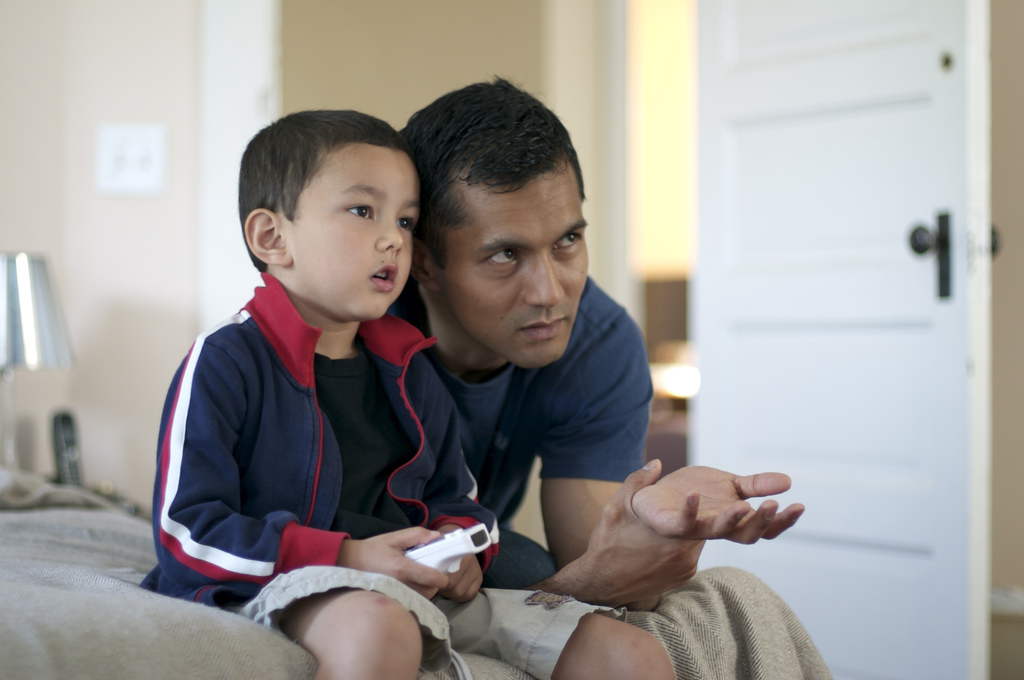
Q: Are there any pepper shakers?
A: No, there are no pepper shakers.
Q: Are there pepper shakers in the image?
A: No, there are no pepper shakers.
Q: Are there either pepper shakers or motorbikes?
A: No, there are no pepper shakers or motorbikes.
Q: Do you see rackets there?
A: No, there are no rackets.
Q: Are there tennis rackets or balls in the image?
A: No, there are no tennis rackets or balls.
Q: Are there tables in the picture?
A: Yes, there is a table.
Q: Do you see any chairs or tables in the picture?
A: Yes, there is a table.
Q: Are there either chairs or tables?
A: Yes, there is a table.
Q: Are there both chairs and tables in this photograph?
A: No, there is a table but no chairs.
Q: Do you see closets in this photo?
A: No, there are no closets.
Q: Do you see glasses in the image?
A: No, there are no glasses.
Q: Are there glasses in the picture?
A: No, there are no glasses.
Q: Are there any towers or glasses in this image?
A: No, there are no glasses or towers.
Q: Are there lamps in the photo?
A: Yes, there is a lamp.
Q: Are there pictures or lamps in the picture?
A: Yes, there is a lamp.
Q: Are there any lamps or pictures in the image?
A: Yes, there is a lamp.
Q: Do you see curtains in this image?
A: No, there are no curtains.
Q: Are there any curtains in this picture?
A: No, there are no curtains.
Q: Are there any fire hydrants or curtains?
A: No, there are no curtains or fire hydrants.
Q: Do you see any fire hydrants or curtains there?
A: No, there are no curtains or fire hydrants.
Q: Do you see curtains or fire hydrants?
A: No, there are no curtains or fire hydrants.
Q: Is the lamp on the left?
A: Yes, the lamp is on the left of the image.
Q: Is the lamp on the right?
A: No, the lamp is on the left of the image.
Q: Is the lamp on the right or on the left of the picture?
A: The lamp is on the left of the image.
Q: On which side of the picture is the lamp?
A: The lamp is on the left of the image.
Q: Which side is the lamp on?
A: The lamp is on the left of the image.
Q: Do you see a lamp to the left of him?
A: Yes, there is a lamp to the left of the boy.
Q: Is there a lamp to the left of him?
A: Yes, there is a lamp to the left of the boy.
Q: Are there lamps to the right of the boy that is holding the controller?
A: No, the lamp is to the left of the boy.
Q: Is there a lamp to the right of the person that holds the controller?
A: No, the lamp is to the left of the boy.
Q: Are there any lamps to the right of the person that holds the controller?
A: No, the lamp is to the left of the boy.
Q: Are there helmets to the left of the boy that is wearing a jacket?
A: No, there is a lamp to the left of the boy.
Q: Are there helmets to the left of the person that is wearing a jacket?
A: No, there is a lamp to the left of the boy.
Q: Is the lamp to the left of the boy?
A: Yes, the lamp is to the left of the boy.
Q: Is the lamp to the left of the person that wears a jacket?
A: Yes, the lamp is to the left of the boy.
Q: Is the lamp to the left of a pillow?
A: No, the lamp is to the left of the boy.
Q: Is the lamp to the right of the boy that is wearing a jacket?
A: No, the lamp is to the left of the boy.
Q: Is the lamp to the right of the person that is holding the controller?
A: No, the lamp is to the left of the boy.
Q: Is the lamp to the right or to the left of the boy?
A: The lamp is to the left of the boy.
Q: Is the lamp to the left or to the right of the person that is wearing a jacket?
A: The lamp is to the left of the boy.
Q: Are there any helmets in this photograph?
A: No, there are no helmets.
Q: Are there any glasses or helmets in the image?
A: No, there are no helmets or glasses.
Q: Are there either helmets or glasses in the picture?
A: No, there are no helmets or glasses.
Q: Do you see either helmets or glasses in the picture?
A: No, there are no helmets or glasses.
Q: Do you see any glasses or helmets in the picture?
A: No, there are no helmets or glasses.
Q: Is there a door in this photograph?
A: Yes, there is a door.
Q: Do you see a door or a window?
A: Yes, there is a door.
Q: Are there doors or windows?
A: Yes, there is a door.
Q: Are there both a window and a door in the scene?
A: No, there is a door but no windows.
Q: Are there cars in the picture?
A: No, there are no cars.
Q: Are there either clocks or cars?
A: No, there are no cars or clocks.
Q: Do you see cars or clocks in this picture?
A: No, there are no cars or clocks.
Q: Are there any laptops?
A: No, there are no laptops.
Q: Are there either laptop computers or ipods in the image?
A: No, there are no laptop computers or ipods.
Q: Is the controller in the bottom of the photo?
A: Yes, the controller is in the bottom of the image.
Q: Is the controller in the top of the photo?
A: No, the controller is in the bottom of the image.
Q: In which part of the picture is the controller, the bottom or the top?
A: The controller is in the bottom of the image.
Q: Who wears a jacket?
A: The boy wears a jacket.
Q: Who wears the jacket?
A: The boy wears a jacket.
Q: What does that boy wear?
A: The boy wears a jacket.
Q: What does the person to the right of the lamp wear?
A: The boy wears a jacket.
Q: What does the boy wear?
A: The boy wears a jacket.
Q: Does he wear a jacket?
A: Yes, the boy wears a jacket.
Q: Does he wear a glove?
A: No, the boy wears a jacket.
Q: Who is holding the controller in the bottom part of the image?
A: The boy is holding the controller.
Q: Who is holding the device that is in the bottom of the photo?
A: The boy is holding the controller.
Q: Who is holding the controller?
A: The boy is holding the controller.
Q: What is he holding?
A: The boy is holding the controller.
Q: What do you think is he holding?
A: The boy is holding the controller.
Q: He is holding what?
A: The boy is holding the controller.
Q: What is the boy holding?
A: The boy is holding the controller.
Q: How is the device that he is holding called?
A: The device is a controller.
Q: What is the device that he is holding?
A: The device is a controller.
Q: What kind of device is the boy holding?
A: The boy is holding the controller.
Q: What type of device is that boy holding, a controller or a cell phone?
A: The boy is holding a controller.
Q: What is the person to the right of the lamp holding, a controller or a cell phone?
A: The boy is holding a controller.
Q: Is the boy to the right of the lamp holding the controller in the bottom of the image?
A: Yes, the boy is holding the controller.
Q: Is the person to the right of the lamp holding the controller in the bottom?
A: Yes, the boy is holding the controller.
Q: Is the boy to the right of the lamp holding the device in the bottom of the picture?
A: Yes, the boy is holding the controller.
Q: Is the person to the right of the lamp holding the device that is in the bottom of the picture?
A: Yes, the boy is holding the controller.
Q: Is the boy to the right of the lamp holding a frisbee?
A: No, the boy is holding the controller.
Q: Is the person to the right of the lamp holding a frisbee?
A: No, the boy is holding the controller.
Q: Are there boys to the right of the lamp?
A: Yes, there is a boy to the right of the lamp.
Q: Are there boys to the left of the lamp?
A: No, the boy is to the right of the lamp.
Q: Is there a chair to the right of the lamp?
A: No, there is a boy to the right of the lamp.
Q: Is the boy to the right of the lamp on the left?
A: Yes, the boy is to the right of the lamp.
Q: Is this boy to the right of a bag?
A: No, the boy is to the right of the lamp.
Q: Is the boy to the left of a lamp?
A: No, the boy is to the right of a lamp.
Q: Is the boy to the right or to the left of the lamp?
A: The boy is to the right of the lamp.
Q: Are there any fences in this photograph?
A: No, there are no fences.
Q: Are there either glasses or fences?
A: No, there are no fences or glasses.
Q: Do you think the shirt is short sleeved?
A: Yes, the shirt is short sleeved.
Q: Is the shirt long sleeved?
A: No, the shirt is short sleeved.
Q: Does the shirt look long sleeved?
A: No, the shirt is short sleeved.